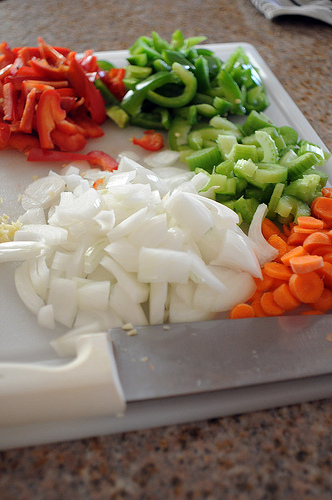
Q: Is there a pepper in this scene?
A: Yes, there are peppers.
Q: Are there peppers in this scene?
A: Yes, there are peppers.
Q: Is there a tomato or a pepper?
A: Yes, there are peppers.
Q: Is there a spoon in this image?
A: No, there are no spoons.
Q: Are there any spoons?
A: No, there are no spoons.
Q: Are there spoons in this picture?
A: No, there are no spoons.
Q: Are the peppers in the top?
A: Yes, the peppers are in the top of the image.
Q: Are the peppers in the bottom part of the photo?
A: No, the peppers are in the top of the image.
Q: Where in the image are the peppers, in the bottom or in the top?
A: The peppers are in the top of the image.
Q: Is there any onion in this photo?
A: Yes, there is an onion.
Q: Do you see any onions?
A: Yes, there is an onion.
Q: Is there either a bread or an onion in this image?
A: Yes, there is an onion.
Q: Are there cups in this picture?
A: No, there are no cups.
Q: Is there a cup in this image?
A: No, there are no cups.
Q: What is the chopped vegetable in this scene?
A: The vegetable is an onion.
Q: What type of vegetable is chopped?
A: The vegetable is an onion.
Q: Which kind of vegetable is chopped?
A: The vegetable is an onion.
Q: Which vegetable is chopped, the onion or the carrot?
A: The onion is chopped.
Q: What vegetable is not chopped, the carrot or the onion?
A: The carrot is not chopped.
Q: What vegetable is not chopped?
A: The vegetable is a carrot.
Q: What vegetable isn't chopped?
A: The vegetable is a carrot.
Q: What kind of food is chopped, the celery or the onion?
A: The onion is chopped.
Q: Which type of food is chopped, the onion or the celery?
A: The onion is chopped.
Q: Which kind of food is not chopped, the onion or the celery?
A: The celery is not chopped.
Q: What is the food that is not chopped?
A: The food is a celery.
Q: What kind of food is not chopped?
A: The food is a celery.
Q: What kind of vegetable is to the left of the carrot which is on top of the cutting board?
A: The vegetable is an onion.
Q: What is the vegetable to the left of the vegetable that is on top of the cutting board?
A: The vegetable is an onion.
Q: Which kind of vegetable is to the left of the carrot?
A: The vegetable is an onion.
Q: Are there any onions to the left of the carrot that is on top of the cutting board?
A: Yes, there is an onion to the left of the carrot.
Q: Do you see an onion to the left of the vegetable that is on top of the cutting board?
A: Yes, there is an onion to the left of the carrot.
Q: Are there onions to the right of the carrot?
A: No, the onion is to the left of the carrot.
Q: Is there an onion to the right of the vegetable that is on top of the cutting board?
A: No, the onion is to the left of the carrot.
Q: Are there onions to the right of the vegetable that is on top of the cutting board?
A: No, the onion is to the left of the carrot.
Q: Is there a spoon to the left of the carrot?
A: No, there is an onion to the left of the carrot.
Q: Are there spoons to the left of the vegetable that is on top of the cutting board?
A: No, there is an onion to the left of the carrot.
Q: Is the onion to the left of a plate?
A: No, the onion is to the left of the carrot.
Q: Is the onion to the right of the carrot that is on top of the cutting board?
A: No, the onion is to the left of the carrot.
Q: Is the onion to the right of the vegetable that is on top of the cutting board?
A: No, the onion is to the left of the carrot.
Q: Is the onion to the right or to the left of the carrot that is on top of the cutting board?
A: The onion is to the left of the carrot.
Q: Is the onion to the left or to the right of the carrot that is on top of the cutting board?
A: The onion is to the left of the carrot.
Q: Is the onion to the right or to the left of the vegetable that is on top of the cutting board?
A: The onion is to the left of the carrot.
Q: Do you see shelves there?
A: No, there are no shelves.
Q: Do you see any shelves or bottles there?
A: No, there are no shelves or bottles.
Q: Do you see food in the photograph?
A: Yes, there is food.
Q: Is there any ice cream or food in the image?
A: Yes, there is food.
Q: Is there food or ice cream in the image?
A: Yes, there is food.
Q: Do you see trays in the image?
A: No, there are no trays.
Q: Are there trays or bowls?
A: No, there are no trays or bowls.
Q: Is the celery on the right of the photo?
A: Yes, the celery is on the right of the image.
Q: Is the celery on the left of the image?
A: No, the celery is on the right of the image.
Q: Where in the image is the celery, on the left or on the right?
A: The celery is on the right of the image.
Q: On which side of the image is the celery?
A: The celery is on the right of the image.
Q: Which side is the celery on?
A: The celery is on the right of the image.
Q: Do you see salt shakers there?
A: No, there are no salt shakers.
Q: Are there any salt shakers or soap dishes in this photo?
A: No, there are no salt shakers or soap dishes.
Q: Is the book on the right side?
A: Yes, the book is on the right of the image.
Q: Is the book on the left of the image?
A: No, the book is on the right of the image.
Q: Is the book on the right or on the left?
A: The book is on the right of the image.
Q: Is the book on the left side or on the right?
A: The book is on the right of the image.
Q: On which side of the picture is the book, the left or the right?
A: The book is on the right of the image.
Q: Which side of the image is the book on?
A: The book is on the right of the image.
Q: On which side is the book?
A: The book is on the right of the image.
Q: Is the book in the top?
A: Yes, the book is in the top of the image.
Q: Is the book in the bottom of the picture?
A: No, the book is in the top of the image.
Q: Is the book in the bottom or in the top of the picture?
A: The book is in the top of the image.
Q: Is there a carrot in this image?
A: Yes, there is a carrot.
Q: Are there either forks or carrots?
A: Yes, there is a carrot.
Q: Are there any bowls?
A: No, there are no bowls.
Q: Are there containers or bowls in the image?
A: No, there are no bowls or containers.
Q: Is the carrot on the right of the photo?
A: Yes, the carrot is on the right of the image.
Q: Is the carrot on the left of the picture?
A: No, the carrot is on the right of the image.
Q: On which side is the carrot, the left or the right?
A: The carrot is on the right of the image.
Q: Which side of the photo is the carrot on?
A: The carrot is on the right of the image.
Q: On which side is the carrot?
A: The carrot is on the right of the image.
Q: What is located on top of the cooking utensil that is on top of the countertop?
A: The carrot is on top of the cutting board.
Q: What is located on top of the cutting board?
A: The carrot is on top of the cutting board.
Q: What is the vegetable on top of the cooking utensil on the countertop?
A: The vegetable is a carrot.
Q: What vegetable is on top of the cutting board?
A: The vegetable is a carrot.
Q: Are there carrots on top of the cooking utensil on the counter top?
A: Yes, there is a carrot on top of the cutting board.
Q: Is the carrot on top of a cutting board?
A: Yes, the carrot is on top of a cutting board.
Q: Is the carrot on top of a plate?
A: No, the carrot is on top of a cutting board.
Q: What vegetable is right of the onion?
A: The vegetable is a carrot.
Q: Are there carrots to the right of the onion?
A: Yes, there is a carrot to the right of the onion.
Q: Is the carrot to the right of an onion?
A: Yes, the carrot is to the right of an onion.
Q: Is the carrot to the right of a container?
A: No, the carrot is to the right of an onion.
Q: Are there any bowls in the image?
A: No, there are no bowls.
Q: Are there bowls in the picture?
A: No, there are no bowls.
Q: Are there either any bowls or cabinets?
A: No, there are no bowls or cabinets.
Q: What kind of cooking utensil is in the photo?
A: The cooking utensil is a cutting board.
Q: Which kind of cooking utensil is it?
A: The cooking utensil is a cutting board.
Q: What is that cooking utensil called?
A: This is a cutting board.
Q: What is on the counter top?
A: The cutting board is on the counter top.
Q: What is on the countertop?
A: The cutting board is on the counter top.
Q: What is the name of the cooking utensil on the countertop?
A: The cooking utensil is a cutting board.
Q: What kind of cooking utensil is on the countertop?
A: The cooking utensil is a cutting board.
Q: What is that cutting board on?
A: The cutting board is on the countertop.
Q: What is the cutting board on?
A: The cutting board is on the countertop.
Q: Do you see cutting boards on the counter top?
A: Yes, there is a cutting board on the counter top.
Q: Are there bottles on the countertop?
A: No, there is a cutting board on the countertop.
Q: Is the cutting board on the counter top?
A: Yes, the cutting board is on the counter top.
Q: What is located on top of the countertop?
A: The cutting board is on top of the countertop.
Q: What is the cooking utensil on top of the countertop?
A: The cooking utensil is a cutting board.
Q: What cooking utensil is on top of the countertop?
A: The cooking utensil is a cutting board.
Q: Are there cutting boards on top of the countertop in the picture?
A: Yes, there is a cutting board on top of the countertop.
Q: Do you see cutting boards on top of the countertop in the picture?
A: Yes, there is a cutting board on top of the countertop.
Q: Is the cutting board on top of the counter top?
A: Yes, the cutting board is on top of the counter top.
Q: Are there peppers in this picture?
A: Yes, there are peppers.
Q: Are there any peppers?
A: Yes, there are peppers.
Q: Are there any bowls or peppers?
A: Yes, there are peppers.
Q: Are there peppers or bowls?
A: Yes, there are peppers.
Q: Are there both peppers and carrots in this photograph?
A: Yes, there are both peppers and carrots.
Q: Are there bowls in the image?
A: No, there are no bowls.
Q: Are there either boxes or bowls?
A: No, there are no bowls or boxes.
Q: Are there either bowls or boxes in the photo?
A: No, there are no bowls or boxes.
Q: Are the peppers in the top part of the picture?
A: Yes, the peppers are in the top of the image.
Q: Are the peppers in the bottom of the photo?
A: No, the peppers are in the top of the image.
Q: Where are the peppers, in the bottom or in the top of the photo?
A: The peppers are in the top of the image.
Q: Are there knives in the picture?
A: Yes, there is a knife.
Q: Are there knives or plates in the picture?
A: Yes, there is a knife.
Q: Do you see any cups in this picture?
A: No, there are no cups.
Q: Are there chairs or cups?
A: No, there are no cups or chairs.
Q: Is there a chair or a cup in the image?
A: No, there are no cups or chairs.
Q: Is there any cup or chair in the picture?
A: No, there are no cups or chairs.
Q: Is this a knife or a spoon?
A: This is a knife.